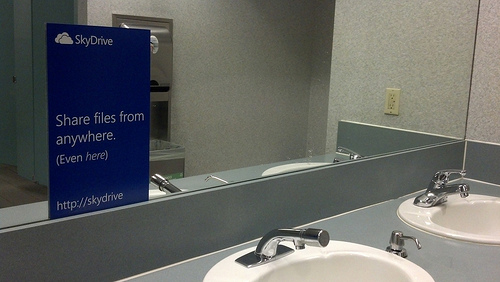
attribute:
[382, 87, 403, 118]
socket — reflecting, reflected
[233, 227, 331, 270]
faucet — metal, silver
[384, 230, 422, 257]
soap dispenser — metal, silver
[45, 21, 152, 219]
sign — blue, rectangular, advertisement, white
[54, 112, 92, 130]
word — white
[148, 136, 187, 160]
bag — plastic, clear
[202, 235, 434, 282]
sink — white, in bathroom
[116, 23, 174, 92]
towel dispenser — silver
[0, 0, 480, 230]
mirror — reflecting, large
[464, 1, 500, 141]
wall — grey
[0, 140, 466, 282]
backsplash — gray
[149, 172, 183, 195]
faucet — reflection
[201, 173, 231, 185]
soap dispenser — reflection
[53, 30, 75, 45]
cloud — white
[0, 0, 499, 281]
photo — without people, bathroom